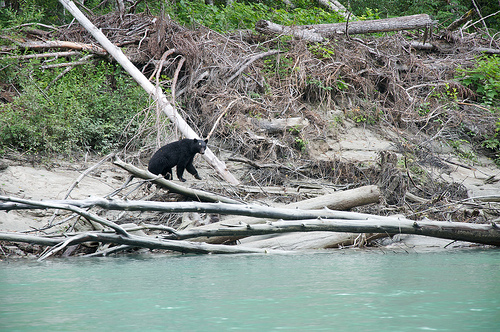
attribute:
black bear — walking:
[138, 128, 214, 188]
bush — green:
[195, 8, 238, 24]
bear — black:
[175, 145, 186, 161]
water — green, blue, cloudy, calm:
[183, 269, 389, 331]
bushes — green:
[27, 91, 123, 127]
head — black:
[194, 136, 209, 155]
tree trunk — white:
[107, 50, 156, 98]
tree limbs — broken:
[311, 161, 362, 192]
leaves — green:
[465, 68, 483, 95]